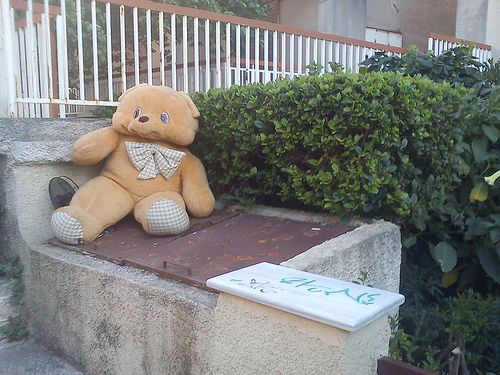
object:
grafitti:
[275, 273, 388, 304]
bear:
[50, 81, 216, 250]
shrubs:
[188, 44, 500, 235]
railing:
[1, 2, 500, 118]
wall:
[1, 118, 402, 375]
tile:
[206, 259, 405, 334]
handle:
[161, 257, 197, 276]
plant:
[381, 289, 500, 373]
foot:
[145, 196, 192, 238]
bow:
[124, 139, 186, 180]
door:
[118, 211, 358, 294]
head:
[109, 83, 202, 146]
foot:
[48, 209, 85, 248]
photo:
[5, 4, 499, 375]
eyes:
[158, 109, 170, 126]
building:
[278, 0, 487, 94]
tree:
[64, 3, 278, 88]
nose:
[134, 114, 151, 125]